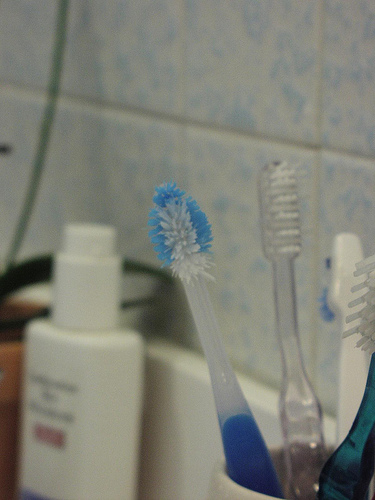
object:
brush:
[185, 414, 302, 496]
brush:
[180, 362, 330, 466]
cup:
[176, 446, 239, 493]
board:
[122, 397, 244, 451]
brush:
[206, 400, 304, 497]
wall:
[160, 387, 244, 487]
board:
[79, 383, 233, 463]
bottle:
[27, 187, 162, 497]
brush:
[136, 214, 304, 497]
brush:
[253, 233, 355, 498]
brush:
[315, 236, 373, 394]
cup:
[193, 420, 373, 498]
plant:
[24, 61, 95, 176]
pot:
[6, 294, 40, 424]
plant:
[18, 59, 86, 258]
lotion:
[28, 215, 139, 496]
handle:
[208, 413, 287, 493]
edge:
[214, 419, 233, 478]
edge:
[129, 385, 142, 492]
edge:
[216, 467, 235, 494]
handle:
[284, 394, 324, 467]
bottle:
[117, 404, 138, 483]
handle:
[201, 338, 241, 397]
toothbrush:
[134, 176, 282, 493]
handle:
[178, 282, 282, 483]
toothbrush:
[253, 159, 328, 495]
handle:
[261, 262, 323, 483]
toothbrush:
[319, 223, 368, 423]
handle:
[335, 326, 369, 455]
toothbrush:
[317, 356, 372, 490]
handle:
[321, 479, 372, 491]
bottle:
[57, 231, 131, 487]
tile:
[186, 137, 256, 193]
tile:
[86, 147, 128, 213]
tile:
[200, 72, 272, 119]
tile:
[118, 69, 187, 104]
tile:
[327, 165, 374, 225]